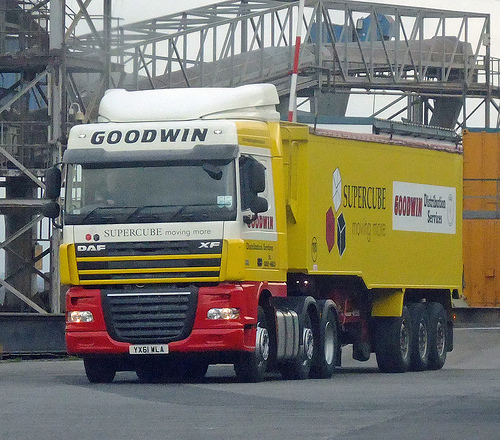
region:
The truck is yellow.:
[60, 79, 465, 377]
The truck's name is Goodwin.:
[88, 128, 220, 155]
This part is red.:
[62, 285, 281, 356]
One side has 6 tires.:
[228, 291, 483, 385]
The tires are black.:
[233, 292, 455, 376]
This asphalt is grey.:
[15, 389, 498, 438]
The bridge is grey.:
[8, 1, 492, 93]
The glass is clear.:
[65, 164, 237, 209]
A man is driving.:
[86, 163, 135, 215]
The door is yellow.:
[465, 132, 499, 309]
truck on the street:
[34, 71, 479, 390]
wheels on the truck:
[358, 308, 453, 366]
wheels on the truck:
[251, 306, 348, 373]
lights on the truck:
[58, 305, 267, 322]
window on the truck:
[68, 161, 229, 215]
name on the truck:
[347, 180, 385, 215]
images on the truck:
[322, 165, 352, 259]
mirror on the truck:
[248, 157, 273, 219]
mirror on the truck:
[44, 163, 62, 223]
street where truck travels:
[21, 365, 471, 431]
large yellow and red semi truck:
[35, 90, 480, 392]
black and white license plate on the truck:
[127, 341, 174, 358]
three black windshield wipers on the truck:
[85, 204, 221, 224]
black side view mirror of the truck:
[240, 153, 271, 226]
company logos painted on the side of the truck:
[307, 152, 466, 263]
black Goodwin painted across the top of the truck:
[81, 126, 216, 156]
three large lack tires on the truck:
[370, 302, 452, 380]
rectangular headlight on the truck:
[63, 306, 98, 328]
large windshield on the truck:
[67, 162, 234, 220]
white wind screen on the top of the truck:
[94, 78, 286, 123]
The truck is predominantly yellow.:
[46, 60, 475, 390]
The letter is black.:
[84, 124, 107, 150]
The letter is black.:
[103, 123, 125, 147]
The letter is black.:
[121, 120, 142, 152]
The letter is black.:
[138, 120, 160, 152]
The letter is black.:
[156, 121, 183, 150]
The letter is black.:
[178, 120, 194, 151]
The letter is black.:
[188, 120, 210, 150]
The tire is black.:
[228, 290, 276, 390]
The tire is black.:
[373, 290, 419, 376]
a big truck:
[50, 70, 472, 390]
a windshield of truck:
[59, 145, 240, 227]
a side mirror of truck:
[246, 159, 267, 194]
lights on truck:
[205, 304, 240, 322]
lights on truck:
[63, 306, 94, 325]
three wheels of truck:
[371, 296, 455, 376]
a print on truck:
[87, 123, 212, 145]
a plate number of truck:
[124, 340, 171, 357]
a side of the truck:
[233, 120, 466, 382]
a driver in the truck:
[81, 169, 129, 217]